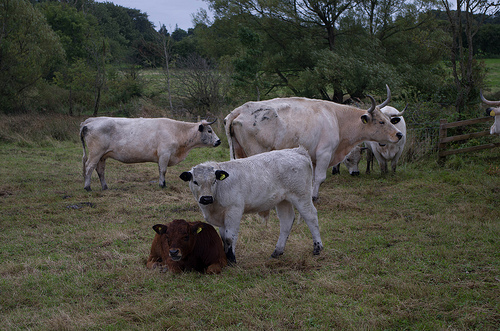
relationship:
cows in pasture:
[77, 88, 415, 272] [3, 2, 497, 328]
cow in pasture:
[146, 219, 229, 274] [3, 2, 497, 328]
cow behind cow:
[189, 148, 329, 261] [146, 219, 229, 274]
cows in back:
[82, 79, 406, 187] [32, 62, 494, 181]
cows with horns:
[82, 79, 406, 187] [354, 81, 407, 120]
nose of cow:
[198, 195, 214, 205] [189, 148, 329, 261]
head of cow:
[182, 161, 226, 204] [189, 148, 329, 261]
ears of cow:
[150, 221, 205, 235] [146, 219, 229, 274]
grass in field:
[9, 147, 496, 331] [3, 2, 497, 328]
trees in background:
[3, 2, 499, 121] [2, 4, 497, 198]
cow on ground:
[146, 219, 229, 274] [9, 147, 496, 331]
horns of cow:
[354, 81, 407, 120] [228, 95, 401, 200]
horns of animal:
[354, 81, 407, 120] [228, 95, 401, 200]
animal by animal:
[189, 148, 329, 261] [146, 219, 229, 274]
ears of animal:
[150, 221, 205, 235] [146, 219, 229, 274]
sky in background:
[102, 1, 411, 31] [2, 4, 497, 198]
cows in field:
[77, 88, 415, 272] [3, 2, 497, 328]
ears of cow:
[180, 171, 229, 181] [189, 148, 329, 261]